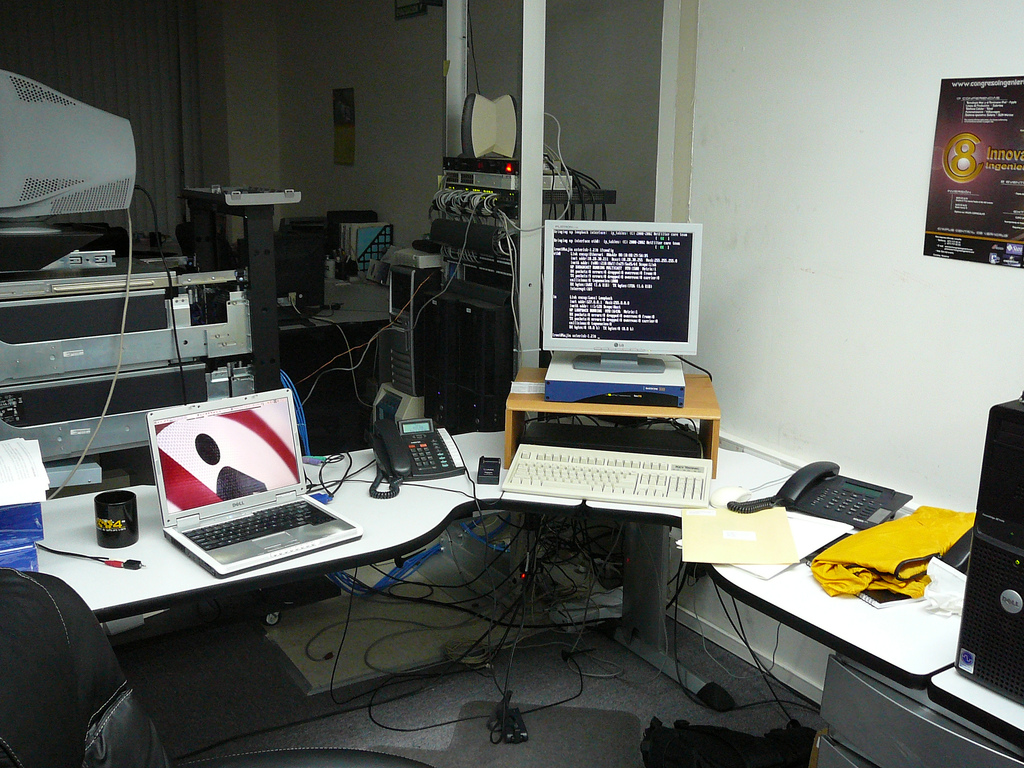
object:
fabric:
[810, 505, 975, 600]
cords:
[302, 517, 623, 733]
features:
[797, 474, 896, 525]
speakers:
[462, 93, 519, 176]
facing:
[462, 95, 479, 161]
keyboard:
[499, 444, 712, 510]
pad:
[672, 476, 679, 479]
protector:
[444, 699, 638, 768]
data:
[0, 74, 1021, 768]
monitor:
[539, 219, 704, 356]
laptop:
[145, 388, 361, 579]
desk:
[2, 418, 1021, 738]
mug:
[95, 492, 139, 550]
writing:
[95, 518, 127, 535]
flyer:
[921, 78, 1024, 270]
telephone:
[370, 418, 465, 500]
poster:
[923, 78, 1022, 271]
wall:
[692, 0, 1023, 512]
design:
[154, 409, 299, 515]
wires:
[306, 505, 626, 687]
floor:
[110, 512, 814, 768]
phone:
[726, 461, 913, 531]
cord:
[34, 540, 145, 570]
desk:
[0, 428, 504, 616]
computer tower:
[953, 392, 1024, 707]